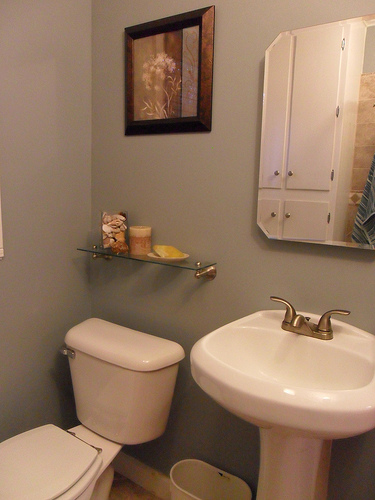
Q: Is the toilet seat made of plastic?
A: Yes, the toilet seat is made of plastic.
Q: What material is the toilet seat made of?
A: The toilet seat is made of plastic.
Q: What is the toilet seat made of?
A: The toilet seat is made of plastic.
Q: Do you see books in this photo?
A: No, there are no books.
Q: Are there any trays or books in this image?
A: No, there are no books or trays.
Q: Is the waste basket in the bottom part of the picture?
A: Yes, the waste basket is in the bottom of the image.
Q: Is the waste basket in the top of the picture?
A: No, the waste basket is in the bottom of the image.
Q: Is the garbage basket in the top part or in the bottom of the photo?
A: The garbage basket is in the bottom of the image.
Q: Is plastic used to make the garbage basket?
A: Yes, the garbage basket is made of plastic.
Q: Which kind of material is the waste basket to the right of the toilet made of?
A: The garbage basket is made of plastic.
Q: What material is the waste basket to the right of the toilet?
A: The garbage basket is made of plastic.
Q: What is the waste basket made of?
A: The garbage basket is made of plastic.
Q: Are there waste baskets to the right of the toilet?
A: Yes, there is a waste basket to the right of the toilet.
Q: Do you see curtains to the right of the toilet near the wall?
A: No, there is a waste basket to the right of the toilet.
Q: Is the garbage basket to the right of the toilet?
A: Yes, the garbage basket is to the right of the toilet.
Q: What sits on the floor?
A: The waste basket sits on the floor.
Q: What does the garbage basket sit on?
A: The garbage basket sits on the floor.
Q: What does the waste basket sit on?
A: The garbage basket sits on the floor.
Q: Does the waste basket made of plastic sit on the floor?
A: Yes, the garbage basket sits on the floor.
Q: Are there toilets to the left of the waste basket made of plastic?
A: Yes, there is a toilet to the left of the waste basket.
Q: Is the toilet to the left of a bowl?
A: No, the toilet is to the left of the waste basket.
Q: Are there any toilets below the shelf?
A: Yes, there is a toilet below the shelf.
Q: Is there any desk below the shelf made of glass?
A: No, there is a toilet below the shelf.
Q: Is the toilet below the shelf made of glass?
A: Yes, the toilet is below the shelf.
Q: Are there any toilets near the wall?
A: Yes, there is a toilet near the wall.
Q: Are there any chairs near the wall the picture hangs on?
A: No, there is a toilet near the wall.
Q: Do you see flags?
A: No, there are no flags.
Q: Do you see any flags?
A: No, there are no flags.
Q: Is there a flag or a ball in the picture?
A: No, there are no flags or balls.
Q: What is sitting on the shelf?
A: The candle is sitting on the shelf.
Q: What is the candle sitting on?
A: The candle is sitting on the shelf.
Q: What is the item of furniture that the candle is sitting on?
A: The piece of furniture is a shelf.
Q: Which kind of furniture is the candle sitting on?
A: The candle is sitting on the shelf.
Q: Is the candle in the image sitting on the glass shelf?
A: Yes, the candle is sitting on the shelf.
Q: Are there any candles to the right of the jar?
A: Yes, there is a candle to the right of the jar.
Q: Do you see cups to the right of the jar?
A: No, there is a candle to the right of the jar.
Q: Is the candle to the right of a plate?
A: No, the candle is to the right of a jar.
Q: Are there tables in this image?
A: No, there are no tables.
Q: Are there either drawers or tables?
A: No, there are no tables or drawers.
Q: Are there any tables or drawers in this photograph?
A: No, there are no tables or drawers.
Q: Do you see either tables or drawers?
A: No, there are no tables or drawers.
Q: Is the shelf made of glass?
A: Yes, the shelf is made of glass.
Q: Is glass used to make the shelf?
A: Yes, the shelf is made of glass.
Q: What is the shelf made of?
A: The shelf is made of glass.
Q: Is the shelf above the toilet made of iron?
A: No, the shelf is made of glass.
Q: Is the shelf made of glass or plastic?
A: The shelf is made of glass.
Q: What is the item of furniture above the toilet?
A: The piece of furniture is a shelf.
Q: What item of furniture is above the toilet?
A: The piece of furniture is a shelf.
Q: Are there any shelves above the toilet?
A: Yes, there is a shelf above the toilet.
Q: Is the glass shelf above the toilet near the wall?
A: Yes, the shelf is above the toilet.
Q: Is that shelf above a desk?
A: No, the shelf is above the toilet.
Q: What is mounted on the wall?
A: The shelf is mounted on the wall.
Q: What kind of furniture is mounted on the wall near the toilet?
A: The piece of furniture is a shelf.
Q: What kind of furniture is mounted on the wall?
A: The piece of furniture is a shelf.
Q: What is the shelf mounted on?
A: The shelf is mounted on the wall.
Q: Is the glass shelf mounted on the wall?
A: Yes, the shelf is mounted on the wall.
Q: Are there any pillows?
A: No, there are no pillows.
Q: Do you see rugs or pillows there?
A: No, there are no pillows or rugs.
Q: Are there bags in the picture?
A: No, there are no bags.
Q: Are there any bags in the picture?
A: No, there are no bags.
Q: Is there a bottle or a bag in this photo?
A: No, there are no bags or bottles.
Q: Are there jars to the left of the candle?
A: Yes, there is a jar to the left of the candle.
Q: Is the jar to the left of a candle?
A: Yes, the jar is to the left of a candle.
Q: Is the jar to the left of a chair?
A: No, the jar is to the left of a candle.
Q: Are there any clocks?
A: No, there are no clocks.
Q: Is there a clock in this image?
A: No, there are no clocks.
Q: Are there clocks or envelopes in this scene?
A: No, there are no clocks or envelopes.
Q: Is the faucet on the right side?
A: Yes, the faucet is on the right of the image.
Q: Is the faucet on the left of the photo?
A: No, the faucet is on the right of the image.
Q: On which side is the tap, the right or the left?
A: The tap is on the right of the image.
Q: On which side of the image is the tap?
A: The tap is on the right of the image.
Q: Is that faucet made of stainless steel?
A: Yes, the faucet is made of stainless steel.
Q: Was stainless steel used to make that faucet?
A: Yes, the faucet is made of stainless steel.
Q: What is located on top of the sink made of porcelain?
A: The tap is on top of the sink.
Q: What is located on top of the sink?
A: The tap is on top of the sink.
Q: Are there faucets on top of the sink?
A: Yes, there is a faucet on top of the sink.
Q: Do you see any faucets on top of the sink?
A: Yes, there is a faucet on top of the sink.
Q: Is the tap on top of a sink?
A: Yes, the tap is on top of a sink.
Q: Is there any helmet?
A: No, there are no helmets.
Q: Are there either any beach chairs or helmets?
A: No, there are no helmets or beach chairs.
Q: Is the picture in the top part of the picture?
A: Yes, the picture is in the top of the image.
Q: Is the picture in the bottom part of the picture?
A: No, the picture is in the top of the image.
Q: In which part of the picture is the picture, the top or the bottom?
A: The picture is in the top of the image.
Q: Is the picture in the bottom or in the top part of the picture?
A: The picture is in the top of the image.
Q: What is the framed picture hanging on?
A: The picture is hanging on the wall.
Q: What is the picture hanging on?
A: The picture is hanging on the wall.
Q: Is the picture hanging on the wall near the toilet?
A: Yes, the picture is hanging on the wall.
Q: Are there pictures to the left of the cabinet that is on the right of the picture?
A: Yes, there is a picture to the left of the cabinet.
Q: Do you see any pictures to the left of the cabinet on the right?
A: Yes, there is a picture to the left of the cabinet.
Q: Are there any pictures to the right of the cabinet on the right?
A: No, the picture is to the left of the cabinet.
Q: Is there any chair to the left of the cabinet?
A: No, there is a picture to the left of the cabinet.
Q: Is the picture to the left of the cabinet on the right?
A: Yes, the picture is to the left of the cabinet.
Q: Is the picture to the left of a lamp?
A: No, the picture is to the left of the cabinet.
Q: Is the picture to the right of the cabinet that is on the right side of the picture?
A: No, the picture is to the left of the cabinet.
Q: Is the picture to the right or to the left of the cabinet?
A: The picture is to the left of the cabinet.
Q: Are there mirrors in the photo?
A: Yes, there is a mirror.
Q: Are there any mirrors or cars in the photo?
A: Yes, there is a mirror.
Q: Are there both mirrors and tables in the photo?
A: No, there is a mirror but no tables.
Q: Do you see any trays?
A: No, there are no trays.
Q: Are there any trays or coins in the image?
A: No, there are no trays or coins.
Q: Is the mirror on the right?
A: Yes, the mirror is on the right of the image.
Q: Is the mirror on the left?
A: No, the mirror is on the right of the image.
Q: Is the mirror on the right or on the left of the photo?
A: The mirror is on the right of the image.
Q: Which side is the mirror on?
A: The mirror is on the right of the image.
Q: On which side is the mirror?
A: The mirror is on the right of the image.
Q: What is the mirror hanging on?
A: The mirror is hanging on the wall.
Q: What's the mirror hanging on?
A: The mirror is hanging on the wall.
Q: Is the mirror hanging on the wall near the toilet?
A: Yes, the mirror is hanging on the wall.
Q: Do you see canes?
A: No, there are no canes.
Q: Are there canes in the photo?
A: No, there are no canes.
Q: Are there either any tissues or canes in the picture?
A: No, there are no canes or tissues.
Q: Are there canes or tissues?
A: No, there are no canes or tissues.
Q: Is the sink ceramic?
A: Yes, the sink is ceramic.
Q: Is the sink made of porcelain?
A: Yes, the sink is made of porcelain.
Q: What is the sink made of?
A: The sink is made of porcelain.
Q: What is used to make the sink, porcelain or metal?
A: The sink is made of porcelain.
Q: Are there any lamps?
A: No, there are no lamps.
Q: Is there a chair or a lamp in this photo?
A: No, there are no lamps or chairs.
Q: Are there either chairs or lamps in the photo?
A: No, there are no lamps or chairs.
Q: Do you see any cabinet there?
A: Yes, there is a cabinet.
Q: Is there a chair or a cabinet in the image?
A: Yes, there is a cabinet.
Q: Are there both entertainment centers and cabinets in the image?
A: No, there is a cabinet but no entertainment centers.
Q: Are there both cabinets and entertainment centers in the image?
A: No, there is a cabinet but no entertainment centers.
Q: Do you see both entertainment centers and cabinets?
A: No, there is a cabinet but no entertainment centers.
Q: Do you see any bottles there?
A: No, there are no bottles.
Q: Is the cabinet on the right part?
A: Yes, the cabinet is on the right of the image.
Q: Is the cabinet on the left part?
A: No, the cabinet is on the right of the image.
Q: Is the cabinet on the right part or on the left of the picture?
A: The cabinet is on the right of the image.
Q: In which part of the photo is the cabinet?
A: The cabinet is on the right of the image.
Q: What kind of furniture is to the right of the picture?
A: The piece of furniture is a cabinet.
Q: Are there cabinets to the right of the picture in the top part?
A: Yes, there is a cabinet to the right of the picture.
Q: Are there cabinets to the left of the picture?
A: No, the cabinet is to the right of the picture.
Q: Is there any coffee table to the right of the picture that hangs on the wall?
A: No, there is a cabinet to the right of the picture.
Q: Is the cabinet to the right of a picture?
A: Yes, the cabinet is to the right of a picture.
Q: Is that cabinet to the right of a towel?
A: No, the cabinet is to the right of a picture.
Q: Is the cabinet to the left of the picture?
A: No, the cabinet is to the right of the picture.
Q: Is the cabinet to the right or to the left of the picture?
A: The cabinet is to the right of the picture.